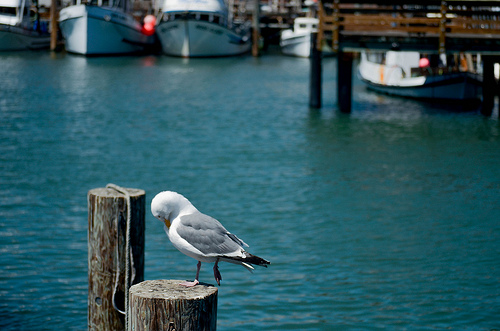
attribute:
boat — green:
[149, 10, 256, 72]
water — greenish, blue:
[279, 120, 498, 327]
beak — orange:
[158, 217, 171, 228]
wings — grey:
[167, 215, 245, 265]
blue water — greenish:
[280, 144, 398, 271]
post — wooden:
[125, 277, 219, 330]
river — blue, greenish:
[2, 47, 497, 326]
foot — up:
[188, 254, 220, 284]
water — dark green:
[311, 156, 439, 193]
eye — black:
[156, 211, 164, 221]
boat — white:
[155, 5, 249, 63]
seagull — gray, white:
[150, 189, 270, 286]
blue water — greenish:
[156, 80, 301, 183]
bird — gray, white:
[141, 179, 255, 287]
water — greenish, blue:
[283, 149, 465, 314]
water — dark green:
[338, 217, 438, 288]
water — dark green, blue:
[1, 47, 498, 327]